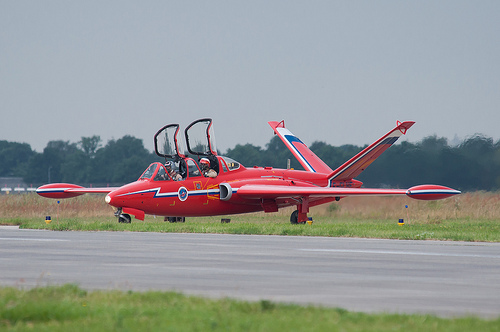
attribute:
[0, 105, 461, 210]
plane — red, white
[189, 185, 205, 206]
line — blue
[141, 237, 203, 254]
airstrip — gray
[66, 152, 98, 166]
tree — green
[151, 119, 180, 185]
cockpit — open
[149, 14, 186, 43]
sky — grey, hazy, white, cloudy, gray, cold, rainy, sunless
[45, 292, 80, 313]
grass — green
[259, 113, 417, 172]
tail — red, white, blue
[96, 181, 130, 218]
nose — white